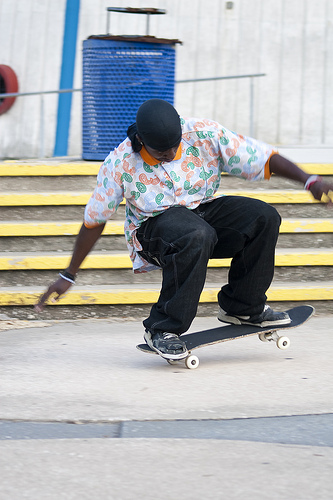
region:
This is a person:
[24, 87, 331, 361]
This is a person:
[44, 95, 330, 395]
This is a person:
[17, 92, 328, 392]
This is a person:
[34, 92, 331, 391]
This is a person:
[26, 91, 329, 399]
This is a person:
[45, 83, 331, 410]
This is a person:
[26, 92, 328, 383]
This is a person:
[18, 100, 330, 345]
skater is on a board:
[79, 116, 327, 347]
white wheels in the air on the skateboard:
[258, 332, 292, 351]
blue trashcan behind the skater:
[74, 31, 181, 105]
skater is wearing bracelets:
[58, 265, 81, 284]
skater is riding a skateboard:
[126, 296, 321, 359]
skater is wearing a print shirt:
[93, 149, 241, 210]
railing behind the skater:
[194, 71, 270, 80]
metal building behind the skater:
[233, 21, 302, 114]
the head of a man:
[115, 111, 213, 170]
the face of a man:
[137, 131, 193, 184]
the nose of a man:
[156, 139, 187, 180]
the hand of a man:
[33, 254, 80, 317]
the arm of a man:
[24, 193, 104, 333]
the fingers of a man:
[10, 233, 126, 326]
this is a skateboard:
[201, 317, 237, 353]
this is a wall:
[234, 21, 287, 71]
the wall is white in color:
[277, 14, 320, 92]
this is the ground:
[219, 353, 271, 397]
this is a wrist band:
[57, 268, 74, 282]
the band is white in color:
[55, 275, 86, 285]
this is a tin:
[96, 44, 125, 73]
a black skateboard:
[136, 303, 318, 365]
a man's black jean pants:
[135, 193, 281, 323]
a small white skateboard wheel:
[188, 354, 199, 368]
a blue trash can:
[82, 34, 184, 162]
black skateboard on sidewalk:
[131, 293, 320, 368]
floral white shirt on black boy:
[69, 119, 277, 275]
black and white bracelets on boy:
[52, 265, 86, 292]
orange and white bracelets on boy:
[300, 170, 321, 188]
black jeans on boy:
[139, 190, 286, 328]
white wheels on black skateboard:
[174, 333, 298, 364]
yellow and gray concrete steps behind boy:
[2, 146, 332, 325]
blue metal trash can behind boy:
[81, 32, 179, 161]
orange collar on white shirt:
[131, 128, 189, 170]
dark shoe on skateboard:
[219, 308, 290, 327]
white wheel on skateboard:
[275, 334, 292, 350]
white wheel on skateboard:
[186, 355, 198, 367]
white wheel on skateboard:
[258, 333, 267, 342]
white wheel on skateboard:
[167, 358, 178, 364]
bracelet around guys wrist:
[57, 268, 78, 282]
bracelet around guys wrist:
[302, 173, 322, 192]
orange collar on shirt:
[140, 150, 158, 167]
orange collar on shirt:
[173, 146, 184, 160]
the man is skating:
[103, 66, 329, 377]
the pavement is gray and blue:
[53, 350, 170, 462]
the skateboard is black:
[161, 309, 301, 348]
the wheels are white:
[166, 334, 218, 390]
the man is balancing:
[141, 280, 303, 377]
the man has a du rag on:
[117, 104, 179, 146]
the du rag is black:
[126, 97, 203, 154]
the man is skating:
[67, 81, 317, 414]